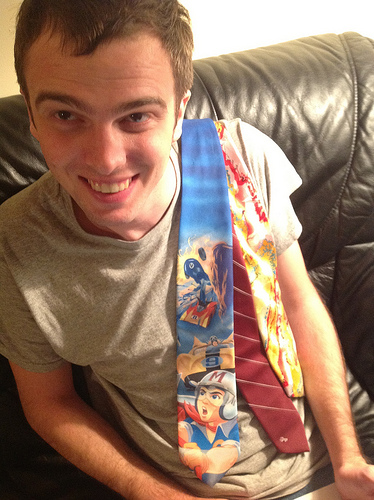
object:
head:
[12, 1, 196, 227]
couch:
[0, 32, 374, 500]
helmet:
[194, 369, 237, 421]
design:
[175, 116, 306, 487]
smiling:
[36, 87, 176, 225]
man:
[1, 0, 374, 495]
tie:
[176, 118, 240, 486]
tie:
[231, 207, 311, 452]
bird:
[182, 258, 210, 302]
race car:
[179, 297, 218, 328]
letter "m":
[210, 371, 227, 383]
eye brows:
[34, 91, 167, 116]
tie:
[214, 122, 305, 398]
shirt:
[0, 119, 331, 500]